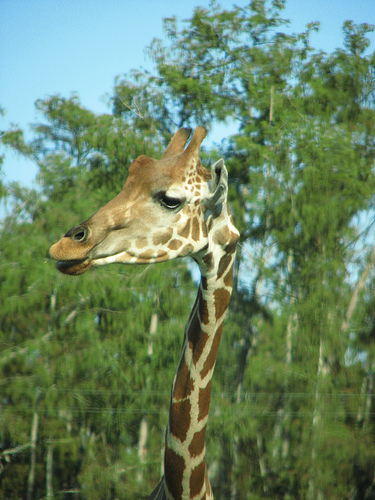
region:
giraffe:
[50, 128, 254, 498]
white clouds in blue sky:
[34, 28, 119, 103]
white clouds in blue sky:
[85, 12, 115, 52]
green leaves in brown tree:
[243, 305, 303, 348]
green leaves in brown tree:
[272, 351, 302, 383]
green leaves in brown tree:
[39, 333, 84, 359]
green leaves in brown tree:
[81, 327, 121, 353]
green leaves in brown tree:
[71, 375, 123, 412]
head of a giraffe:
[30, 126, 279, 287]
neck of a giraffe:
[144, 269, 259, 484]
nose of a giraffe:
[51, 220, 99, 244]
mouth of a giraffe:
[38, 243, 94, 282]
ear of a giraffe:
[201, 149, 229, 191]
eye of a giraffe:
[163, 187, 183, 211]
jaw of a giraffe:
[54, 250, 103, 280]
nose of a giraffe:
[63, 225, 74, 236]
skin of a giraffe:
[211, 264, 225, 291]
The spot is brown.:
[175, 217, 192, 237]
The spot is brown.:
[166, 236, 183, 253]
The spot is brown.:
[154, 246, 172, 263]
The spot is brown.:
[133, 246, 157, 266]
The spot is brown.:
[187, 456, 207, 497]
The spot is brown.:
[160, 443, 187, 498]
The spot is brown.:
[167, 395, 193, 444]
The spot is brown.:
[186, 423, 205, 459]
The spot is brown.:
[195, 377, 210, 424]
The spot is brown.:
[199, 249, 217, 275]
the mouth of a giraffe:
[40, 217, 126, 307]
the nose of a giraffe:
[45, 206, 113, 285]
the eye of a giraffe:
[150, 186, 184, 222]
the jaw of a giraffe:
[126, 218, 207, 275]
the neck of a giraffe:
[147, 262, 291, 481]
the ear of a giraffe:
[196, 168, 256, 230]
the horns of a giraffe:
[148, 7, 248, 193]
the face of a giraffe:
[50, 169, 212, 286]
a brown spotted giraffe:
[48, 164, 278, 447]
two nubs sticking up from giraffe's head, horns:
[163, 117, 214, 168]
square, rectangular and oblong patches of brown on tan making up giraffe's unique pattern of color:
[166, 169, 226, 489]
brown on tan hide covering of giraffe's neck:
[163, 264, 233, 499]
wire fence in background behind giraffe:
[5, 379, 371, 422]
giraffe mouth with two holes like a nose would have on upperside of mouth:
[43, 205, 147, 275]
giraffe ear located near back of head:
[197, 149, 242, 224]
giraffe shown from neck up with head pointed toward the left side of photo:
[42, 99, 308, 494]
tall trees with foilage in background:
[247, 47, 374, 499]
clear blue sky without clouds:
[5, 4, 129, 96]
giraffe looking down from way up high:
[42, 121, 249, 282]